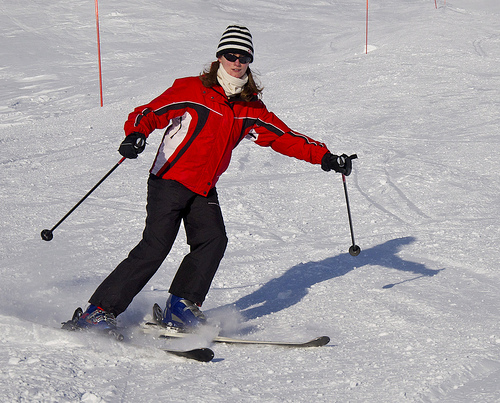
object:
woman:
[64, 25, 351, 335]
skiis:
[142, 323, 329, 347]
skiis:
[164, 346, 215, 362]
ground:
[0, 0, 499, 402]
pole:
[49, 157, 126, 231]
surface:
[0, 0, 499, 402]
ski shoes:
[164, 295, 206, 331]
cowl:
[217, 63, 249, 96]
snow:
[0, 0, 499, 401]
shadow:
[202, 237, 438, 324]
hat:
[216, 24, 254, 63]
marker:
[434, 0, 437, 9]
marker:
[366, 0, 370, 55]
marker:
[93, 0, 102, 107]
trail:
[353, 167, 411, 226]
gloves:
[321, 153, 353, 177]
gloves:
[118, 132, 146, 159]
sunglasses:
[223, 53, 252, 64]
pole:
[341, 172, 355, 245]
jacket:
[123, 74, 328, 196]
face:
[221, 53, 250, 78]